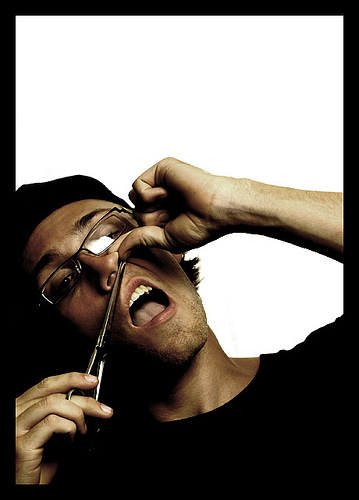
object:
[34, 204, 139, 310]
glasses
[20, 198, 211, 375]
man's face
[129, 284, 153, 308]
teeth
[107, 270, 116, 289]
nose hairs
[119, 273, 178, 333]
mouth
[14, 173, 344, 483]
man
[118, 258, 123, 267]
nose hairs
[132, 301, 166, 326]
tongue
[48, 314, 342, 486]
shirt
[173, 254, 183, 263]
ear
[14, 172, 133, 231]
beret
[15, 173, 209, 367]
head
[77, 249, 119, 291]
nose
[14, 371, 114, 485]
hand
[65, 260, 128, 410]
scissors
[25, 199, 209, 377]
face